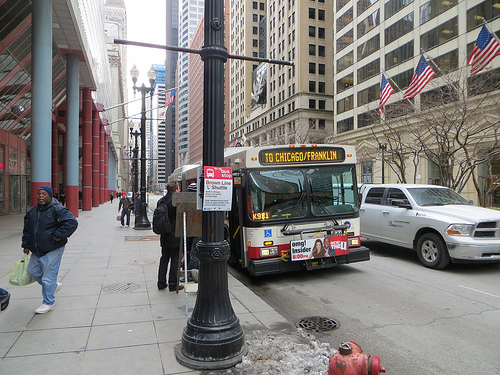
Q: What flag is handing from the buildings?
A: American.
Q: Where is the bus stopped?
A: On side of road.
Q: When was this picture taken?
A: Daytime.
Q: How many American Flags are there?
A: 4.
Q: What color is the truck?
A: White.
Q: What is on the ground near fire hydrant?
A: Snow.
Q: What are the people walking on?
A: Sidewalk.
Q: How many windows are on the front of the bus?
A: 2.